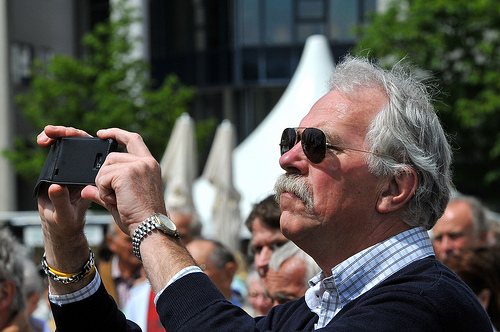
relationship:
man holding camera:
[35, 55, 499, 332] [31, 134, 115, 195]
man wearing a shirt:
[35, 55, 499, 332] [306, 227, 432, 326]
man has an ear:
[35, 55, 499, 332] [376, 162, 418, 213]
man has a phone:
[35, 55, 499, 332] [31, 134, 115, 195]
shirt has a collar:
[306, 227, 432, 326] [333, 227, 445, 303]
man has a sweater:
[35, 55, 499, 332] [44, 272, 499, 332]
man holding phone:
[35, 55, 499, 332] [31, 134, 115, 195]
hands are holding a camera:
[34, 125, 179, 231] [31, 134, 115, 195]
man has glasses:
[35, 55, 499, 332] [280, 125, 404, 168]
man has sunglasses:
[35, 55, 499, 332] [280, 125, 404, 168]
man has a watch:
[35, 55, 499, 332] [129, 213, 180, 258]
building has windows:
[144, 1, 414, 140] [235, 44, 294, 84]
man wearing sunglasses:
[35, 55, 499, 332] [280, 125, 404, 168]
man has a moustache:
[35, 55, 499, 332] [276, 176, 315, 211]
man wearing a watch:
[35, 55, 499, 332] [129, 213, 180, 258]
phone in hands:
[31, 134, 115, 195] [34, 125, 179, 231]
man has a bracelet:
[35, 55, 499, 332] [43, 247, 97, 285]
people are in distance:
[0, 196, 499, 319] [6, 6, 499, 261]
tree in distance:
[354, 0, 499, 213] [6, 6, 499, 261]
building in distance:
[144, 1, 414, 140] [6, 6, 499, 261]